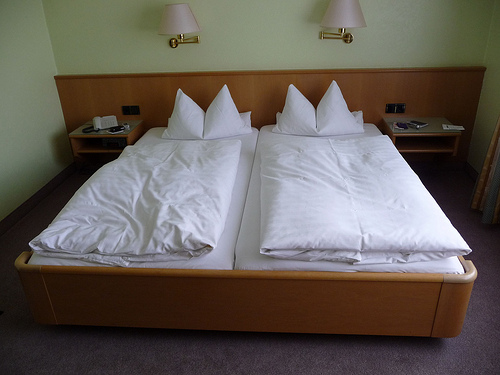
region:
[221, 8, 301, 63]
The wall is off white.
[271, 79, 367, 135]
The pillow is white.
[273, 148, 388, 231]
The bed is white.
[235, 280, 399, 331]
The bed is made of wood.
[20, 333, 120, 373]
The carpet is gray.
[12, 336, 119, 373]
Carpet is on the floor.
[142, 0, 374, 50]
Two lights are on the wall.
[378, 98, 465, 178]
A nightstand.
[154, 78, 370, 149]
Pillows are on the bed.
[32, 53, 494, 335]
a king size bed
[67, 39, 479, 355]
a bed with two twin size mattresses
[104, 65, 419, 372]
a bed with two mattresses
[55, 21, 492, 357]
a bed with white sheets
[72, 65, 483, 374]
a bed with white blankets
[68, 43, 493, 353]
a bed with white pillows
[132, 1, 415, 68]
two lamps on the wall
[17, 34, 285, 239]
a night stand with a book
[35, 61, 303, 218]
a night stand next to the bed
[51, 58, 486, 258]
night stand on each side of the bed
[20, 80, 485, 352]
two mattresses pushed together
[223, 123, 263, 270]
line dividing the mattresses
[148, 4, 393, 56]
two small lamps on the wall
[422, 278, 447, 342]
thin black line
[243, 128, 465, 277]
white duvet folded on top of the bed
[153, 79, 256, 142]
fluffy white pillow that is bent in the middle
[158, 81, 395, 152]
two white pillows on the bed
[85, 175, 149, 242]
wrinkle in the duvet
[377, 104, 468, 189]
brown bedside table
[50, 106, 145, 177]
bedside table with various objects on it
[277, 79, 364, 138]
White pillow on bed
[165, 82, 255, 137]
White pillow on bed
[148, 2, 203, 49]
Small lamp above bed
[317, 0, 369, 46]
Small lamp above bed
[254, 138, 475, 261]
White comforter on bed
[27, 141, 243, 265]
White comforter on bed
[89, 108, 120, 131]
White telephone on nightstand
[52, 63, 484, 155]
Wooden headboard behind bed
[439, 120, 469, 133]
White paper on top of nightstand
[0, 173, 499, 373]
Carpet is dark purple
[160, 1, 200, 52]
Small lamp on top of bed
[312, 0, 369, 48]
Small lamp on top of bed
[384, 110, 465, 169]
Nightstand next to bed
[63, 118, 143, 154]
Nightstand next to bed